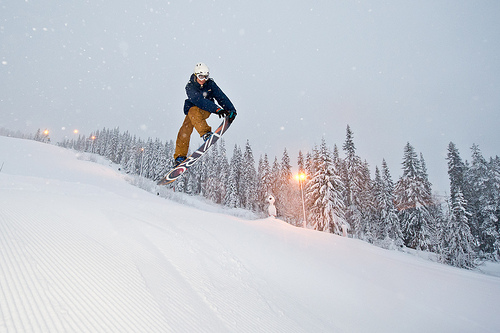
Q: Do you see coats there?
A: Yes, there is a coat.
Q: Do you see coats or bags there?
A: Yes, there is a coat.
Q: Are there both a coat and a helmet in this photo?
A: Yes, there are both a coat and a helmet.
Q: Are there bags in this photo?
A: No, there are no bags.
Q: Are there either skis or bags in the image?
A: No, there are no bags or skis.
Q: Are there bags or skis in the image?
A: No, there are no bags or skis.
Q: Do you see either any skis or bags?
A: No, there are no bags or skis.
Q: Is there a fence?
A: No, there are no fences.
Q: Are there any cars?
A: No, there are no cars.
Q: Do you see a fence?
A: No, there are no fences.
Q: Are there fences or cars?
A: No, there are no fences or cars.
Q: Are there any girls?
A: No, there are no girls.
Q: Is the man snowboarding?
A: Yes, the man is snowboarding.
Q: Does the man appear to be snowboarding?
A: Yes, the man is snowboarding.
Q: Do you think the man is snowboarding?
A: Yes, the man is snowboarding.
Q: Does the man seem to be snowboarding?
A: Yes, the man is snowboarding.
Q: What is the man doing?
A: The man is snowboarding.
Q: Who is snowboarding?
A: The man is snowboarding.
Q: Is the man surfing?
A: No, the man is snowboarding.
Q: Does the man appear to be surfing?
A: No, the man is snowboarding.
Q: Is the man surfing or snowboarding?
A: The man is snowboarding.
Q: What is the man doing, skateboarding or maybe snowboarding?
A: The man is snowboarding.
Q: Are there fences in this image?
A: No, there are no fences.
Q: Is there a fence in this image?
A: No, there are no fences.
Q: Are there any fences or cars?
A: No, there are no fences or cars.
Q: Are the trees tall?
A: Yes, the trees are tall.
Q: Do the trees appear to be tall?
A: Yes, the trees are tall.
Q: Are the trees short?
A: No, the trees are tall.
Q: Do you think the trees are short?
A: No, the trees are tall.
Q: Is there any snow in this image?
A: Yes, there is snow.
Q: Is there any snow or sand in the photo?
A: Yes, there is snow.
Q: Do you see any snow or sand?
A: Yes, there is snow.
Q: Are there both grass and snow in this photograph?
A: No, there is snow but no grass.